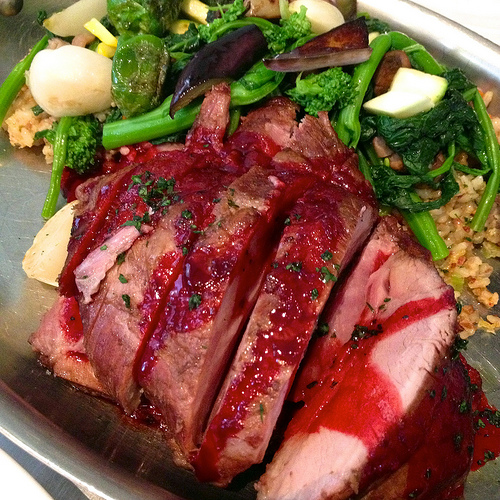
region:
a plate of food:
[10, 16, 494, 489]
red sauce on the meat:
[119, 213, 355, 387]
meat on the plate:
[61, 188, 424, 478]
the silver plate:
[10, 165, 31, 415]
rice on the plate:
[443, 217, 498, 312]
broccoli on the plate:
[371, 113, 483, 248]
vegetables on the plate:
[30, 27, 488, 192]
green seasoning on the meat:
[135, 173, 185, 219]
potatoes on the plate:
[32, 45, 108, 101]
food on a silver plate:
[11, 5, 494, 395]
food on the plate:
[421, 181, 466, 223]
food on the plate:
[376, 131, 424, 178]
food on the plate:
[291, 26, 323, 62]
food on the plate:
[122, 63, 194, 128]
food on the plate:
[351, 330, 439, 438]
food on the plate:
[241, 280, 318, 405]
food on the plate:
[231, 232, 335, 306]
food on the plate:
[188, 198, 271, 285]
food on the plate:
[122, 165, 225, 229]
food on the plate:
[91, 173, 192, 243]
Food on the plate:
[78, 31, 443, 369]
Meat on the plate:
[190, 241, 380, 416]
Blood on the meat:
[224, 256, 369, 409]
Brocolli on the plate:
[297, 71, 370, 122]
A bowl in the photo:
[36, 424, 108, 489]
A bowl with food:
[1, 148, 41, 228]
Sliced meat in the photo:
[110, 202, 395, 434]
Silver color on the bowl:
[404, 6, 483, 65]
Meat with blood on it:
[107, 175, 379, 370]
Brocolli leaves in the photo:
[37, 138, 84, 180]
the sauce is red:
[45, 130, 370, 445]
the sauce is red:
[90, 182, 325, 357]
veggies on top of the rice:
[59, 20, 461, 225]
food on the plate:
[321, 330, 433, 443]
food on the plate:
[153, 273, 245, 353]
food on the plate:
[123, 283, 183, 329]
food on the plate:
[45, 218, 136, 310]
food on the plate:
[393, 196, 480, 313]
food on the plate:
[341, 60, 438, 163]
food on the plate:
[258, 39, 362, 114]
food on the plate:
[130, 8, 262, 53]